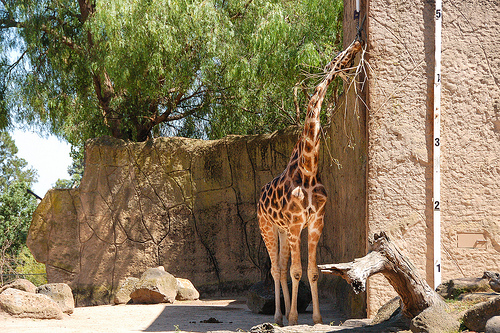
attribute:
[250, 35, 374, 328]
giraffe — tall, eating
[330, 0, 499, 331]
wall — stone, beige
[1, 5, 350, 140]
tree — green color, green colored, green in color, green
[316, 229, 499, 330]
tree stump — old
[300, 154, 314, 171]
spot — dark brown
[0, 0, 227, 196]
sky — blue, white, clear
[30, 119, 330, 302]
wall — brown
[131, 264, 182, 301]
rock — brown